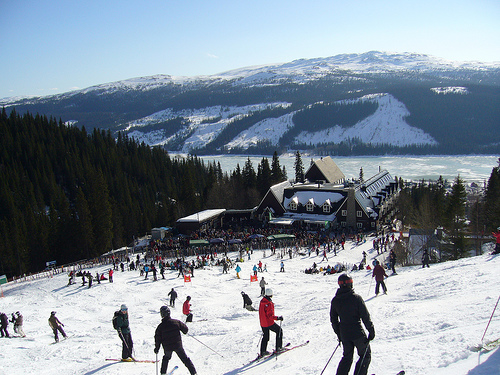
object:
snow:
[231, 120, 281, 145]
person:
[256, 285, 284, 357]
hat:
[118, 303, 127, 312]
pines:
[1, 110, 29, 284]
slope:
[1, 222, 498, 373]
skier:
[47, 310, 67, 340]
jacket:
[331, 285, 372, 339]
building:
[176, 207, 228, 239]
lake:
[162, 154, 495, 183]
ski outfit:
[245, 287, 309, 365]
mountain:
[1, 52, 499, 154]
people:
[329, 272, 373, 374]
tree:
[94, 197, 114, 257]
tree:
[267, 146, 282, 186]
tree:
[444, 171, 468, 221]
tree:
[153, 190, 172, 224]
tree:
[232, 156, 242, 209]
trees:
[57, 121, 98, 263]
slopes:
[106, 82, 491, 146]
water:
[374, 160, 482, 182]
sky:
[0, 0, 499, 102]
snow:
[0, 234, 497, 374]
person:
[152, 305, 196, 374]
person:
[112, 302, 134, 359]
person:
[372, 259, 387, 295]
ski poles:
[256, 329, 265, 350]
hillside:
[3, 111, 233, 302]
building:
[224, 157, 405, 233]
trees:
[485, 170, 500, 237]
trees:
[43, 123, 65, 273]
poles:
[357, 338, 369, 375]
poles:
[277, 317, 287, 361]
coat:
[259, 296, 275, 326]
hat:
[257, 286, 273, 296]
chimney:
[345, 187, 357, 231]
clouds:
[201, 45, 228, 65]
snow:
[243, 355, 303, 374]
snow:
[296, 304, 323, 340]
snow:
[25, 345, 92, 373]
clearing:
[433, 80, 463, 95]